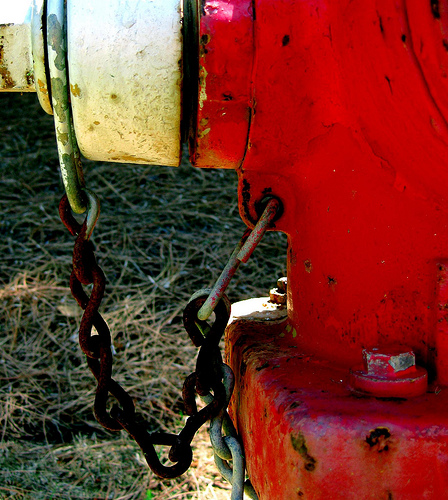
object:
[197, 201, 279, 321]
hook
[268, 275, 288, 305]
bolt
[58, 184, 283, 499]
chain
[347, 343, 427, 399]
nut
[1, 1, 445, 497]
hydrant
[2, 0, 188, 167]
arm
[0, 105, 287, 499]
grass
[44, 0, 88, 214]
ring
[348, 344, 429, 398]
cap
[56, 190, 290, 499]
chain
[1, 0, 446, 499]
fire hydrant